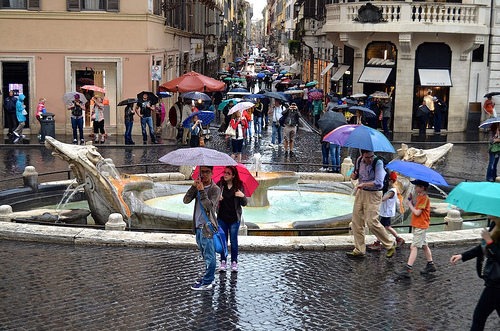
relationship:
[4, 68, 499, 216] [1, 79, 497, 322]
umbrellas in towns center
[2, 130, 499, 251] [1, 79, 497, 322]
fountain in towns center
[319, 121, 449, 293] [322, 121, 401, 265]
children walking with man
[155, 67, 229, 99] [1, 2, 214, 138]
big red umbrella on corner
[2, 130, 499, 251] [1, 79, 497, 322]
fountain of water in square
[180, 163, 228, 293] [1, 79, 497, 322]
man looking at camera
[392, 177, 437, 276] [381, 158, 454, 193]
children holding an umbrella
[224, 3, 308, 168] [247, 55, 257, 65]
background has a car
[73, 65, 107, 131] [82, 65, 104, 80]
window has dior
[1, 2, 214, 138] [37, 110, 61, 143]
building front has trashcan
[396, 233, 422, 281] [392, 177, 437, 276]
leg of children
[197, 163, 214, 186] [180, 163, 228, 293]
face of man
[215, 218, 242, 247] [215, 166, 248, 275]
thighs of woman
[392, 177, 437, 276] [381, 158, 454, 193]
children wearing blue umbrella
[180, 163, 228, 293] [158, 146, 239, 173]
man with gray umbrella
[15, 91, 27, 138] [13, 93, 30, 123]
woman in a blue raincoat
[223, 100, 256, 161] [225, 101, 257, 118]
woman with a white umbrella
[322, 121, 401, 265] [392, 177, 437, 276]
man looking at children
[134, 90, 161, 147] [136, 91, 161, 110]
man holding black umbrella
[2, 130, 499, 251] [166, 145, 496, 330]
fountain behind people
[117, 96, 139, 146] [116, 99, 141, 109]
woman with a black umbrella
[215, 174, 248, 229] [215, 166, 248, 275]
brown jacketed woman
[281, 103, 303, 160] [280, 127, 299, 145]
man with tan shorts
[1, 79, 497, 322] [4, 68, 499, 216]
rain protection umbrellas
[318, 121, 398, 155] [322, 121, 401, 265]
umbrella for rain protection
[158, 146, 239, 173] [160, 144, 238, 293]
umbrella for rain protection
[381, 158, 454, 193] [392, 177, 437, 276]
umbrella for rain children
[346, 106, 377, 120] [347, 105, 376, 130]
umbrella for rain protection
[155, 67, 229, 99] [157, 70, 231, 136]
umbrella for rain protection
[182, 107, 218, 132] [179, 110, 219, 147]
umbrella for rain protection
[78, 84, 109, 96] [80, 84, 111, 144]
umbrella for rain protection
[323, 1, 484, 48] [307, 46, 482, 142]
balcony above shop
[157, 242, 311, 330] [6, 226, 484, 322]
reflection on ground